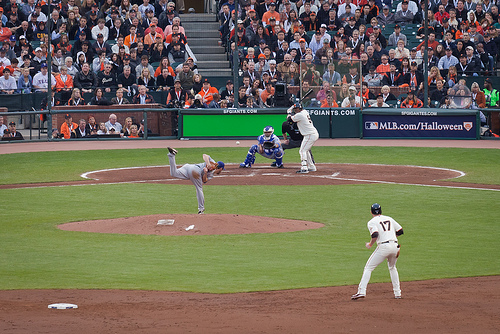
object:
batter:
[286, 102, 320, 175]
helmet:
[293, 103, 302, 111]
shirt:
[287, 110, 318, 136]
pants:
[298, 134, 319, 170]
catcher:
[239, 125, 284, 168]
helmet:
[263, 126, 274, 133]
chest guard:
[260, 135, 275, 154]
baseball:
[236, 140, 240, 144]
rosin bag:
[185, 225, 195, 232]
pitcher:
[166, 146, 227, 215]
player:
[351, 203, 405, 300]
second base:
[47, 302, 79, 309]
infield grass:
[0, 181, 499, 294]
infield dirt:
[0, 162, 500, 332]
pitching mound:
[53, 214, 326, 237]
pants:
[167, 153, 206, 211]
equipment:
[239, 125, 284, 168]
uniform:
[287, 109, 320, 170]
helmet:
[371, 203, 382, 215]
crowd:
[0, 0, 500, 108]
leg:
[166, 147, 188, 180]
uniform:
[356, 215, 405, 296]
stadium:
[0, 0, 500, 334]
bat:
[288, 88, 315, 110]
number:
[380, 220, 391, 232]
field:
[0, 138, 500, 333]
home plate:
[262, 172, 281, 176]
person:
[262, 2, 281, 27]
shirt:
[262, 11, 280, 25]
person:
[483, 78, 498, 107]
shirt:
[481, 88, 499, 106]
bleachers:
[0, 0, 500, 109]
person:
[154, 57, 176, 77]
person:
[91, 19, 110, 40]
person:
[32, 21, 48, 41]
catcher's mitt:
[263, 140, 275, 149]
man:
[60, 114, 78, 138]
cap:
[65, 114, 72, 119]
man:
[438, 47, 459, 76]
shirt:
[437, 55, 459, 70]